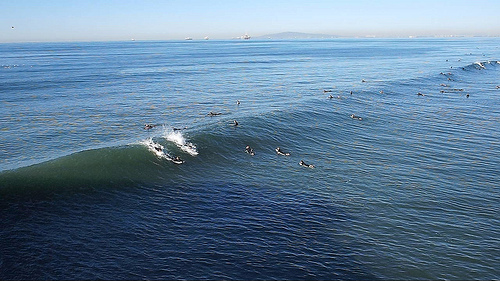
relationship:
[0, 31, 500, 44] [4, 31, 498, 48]
distance in distance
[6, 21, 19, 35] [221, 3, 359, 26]
item in sky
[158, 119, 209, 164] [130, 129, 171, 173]
surfer make splash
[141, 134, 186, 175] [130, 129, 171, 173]
surfer make splash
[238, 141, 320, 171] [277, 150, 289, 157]
people on surfboards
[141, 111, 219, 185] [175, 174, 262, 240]
boats on water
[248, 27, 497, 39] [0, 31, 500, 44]
mountain on distance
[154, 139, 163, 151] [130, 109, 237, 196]
person on wave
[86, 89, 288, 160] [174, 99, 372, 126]
individuals on wave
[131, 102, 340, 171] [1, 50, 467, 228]
people over wave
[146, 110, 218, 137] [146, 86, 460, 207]
people toward wave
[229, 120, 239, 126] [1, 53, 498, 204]
person on wave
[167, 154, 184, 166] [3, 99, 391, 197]
person rides wave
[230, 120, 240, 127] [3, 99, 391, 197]
person rides wave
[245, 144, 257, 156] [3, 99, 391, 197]
person rides wave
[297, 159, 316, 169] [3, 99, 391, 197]
people rides wave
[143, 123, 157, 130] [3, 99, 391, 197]
people rides wave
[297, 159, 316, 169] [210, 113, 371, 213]
people in water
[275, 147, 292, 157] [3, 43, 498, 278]
people in water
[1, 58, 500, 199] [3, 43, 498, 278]
wave across water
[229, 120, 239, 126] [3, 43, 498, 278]
person in water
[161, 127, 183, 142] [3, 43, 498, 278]
splashes in water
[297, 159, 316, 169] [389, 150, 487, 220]
people in water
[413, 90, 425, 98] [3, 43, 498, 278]
person in water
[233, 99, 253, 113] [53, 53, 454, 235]
person in water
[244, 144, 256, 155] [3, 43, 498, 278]
person in water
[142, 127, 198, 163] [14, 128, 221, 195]
splashes on wave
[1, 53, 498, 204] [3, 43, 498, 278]
wave in water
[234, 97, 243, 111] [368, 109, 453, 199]
person in water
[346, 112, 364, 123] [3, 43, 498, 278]
person in water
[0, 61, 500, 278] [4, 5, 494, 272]
ripple in water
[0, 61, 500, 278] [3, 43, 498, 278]
ripple in water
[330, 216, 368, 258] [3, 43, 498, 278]
ripple in water